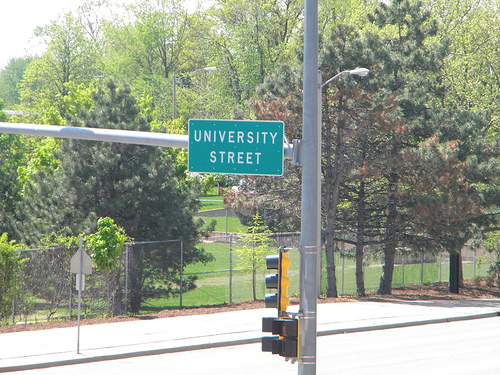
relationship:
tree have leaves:
[253, 25, 296, 50] [379, 39, 392, 66]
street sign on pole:
[176, 104, 293, 180] [60, 120, 116, 148]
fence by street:
[207, 229, 252, 261] [356, 345, 418, 374]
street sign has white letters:
[176, 104, 293, 180] [241, 138, 281, 146]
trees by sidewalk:
[123, 26, 171, 40] [178, 318, 239, 335]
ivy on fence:
[87, 233, 141, 264] [207, 229, 252, 261]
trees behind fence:
[123, 26, 171, 40] [207, 229, 252, 261]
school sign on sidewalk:
[67, 240, 112, 275] [178, 318, 239, 335]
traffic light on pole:
[249, 242, 303, 310] [60, 120, 116, 148]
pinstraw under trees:
[435, 287, 449, 291] [123, 26, 171, 40]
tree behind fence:
[253, 25, 296, 50] [207, 229, 252, 261]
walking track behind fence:
[194, 273, 235, 290] [207, 229, 252, 261]